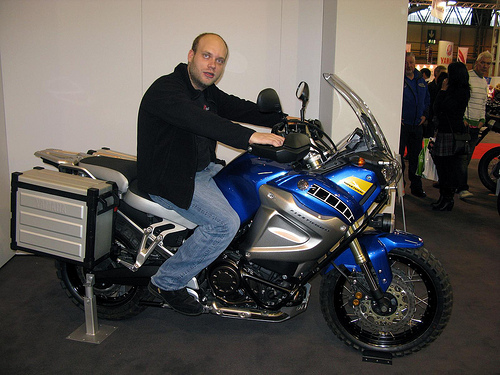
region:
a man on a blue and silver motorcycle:
[135, 32, 268, 332]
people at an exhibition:
[401, 49, 496, 215]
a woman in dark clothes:
[430, 62, 470, 213]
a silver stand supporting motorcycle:
[70, 272, 113, 348]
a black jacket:
[136, 73, 232, 206]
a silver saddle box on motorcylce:
[10, 168, 120, 268]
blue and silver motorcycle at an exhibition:
[28, 129, 450, 362]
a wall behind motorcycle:
[6, 5, 399, 228]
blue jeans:
[153, 181, 238, 287]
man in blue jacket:
[401, 53, 429, 200]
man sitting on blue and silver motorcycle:
[37, 27, 451, 358]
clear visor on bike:
[319, 69, 394, 161]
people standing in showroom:
[402, 50, 469, 185]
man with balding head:
[185, 28, 232, 93]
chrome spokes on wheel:
[395, 267, 422, 327]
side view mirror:
[289, 75, 311, 126]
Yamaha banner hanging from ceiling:
[435, 38, 454, 70]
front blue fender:
[312, 231, 427, 277]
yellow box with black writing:
[334, 173, 376, 198]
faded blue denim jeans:
[145, 170, 241, 295]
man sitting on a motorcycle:
[12, 20, 478, 351]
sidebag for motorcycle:
[2, 140, 122, 282]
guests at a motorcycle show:
[392, 30, 498, 207]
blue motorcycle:
[10, 15, 451, 355]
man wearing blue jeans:
[93, 12, 331, 317]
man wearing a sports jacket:
[104, 20, 343, 304]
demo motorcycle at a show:
[26, 22, 468, 353]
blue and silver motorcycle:
[29, 5, 469, 357]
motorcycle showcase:
[8, 11, 497, 369]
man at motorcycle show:
[67, 9, 309, 314]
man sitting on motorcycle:
[103, 23, 432, 327]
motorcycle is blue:
[211, 136, 443, 338]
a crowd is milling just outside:
[400, 21, 499, 193]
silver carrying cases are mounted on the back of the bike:
[8, 141, 129, 260]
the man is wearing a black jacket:
[122, 69, 286, 191]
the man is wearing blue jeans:
[140, 159, 242, 300]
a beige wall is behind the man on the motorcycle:
[3, 4, 401, 188]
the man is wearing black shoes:
[147, 274, 222, 318]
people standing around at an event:
[385, 23, 498, 184]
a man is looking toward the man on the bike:
[465, 44, 498, 111]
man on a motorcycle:
[118, 28, 288, 323]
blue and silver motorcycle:
[38, 75, 455, 364]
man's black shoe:
[147, 275, 207, 318]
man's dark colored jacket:
[123, 60, 283, 203]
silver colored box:
[8, 162, 118, 276]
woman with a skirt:
[421, 59, 473, 219]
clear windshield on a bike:
[317, 71, 400, 158]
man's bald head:
[190, 27, 228, 47]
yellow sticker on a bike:
[333, 173, 373, 194]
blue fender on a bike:
[326, 227, 425, 297]